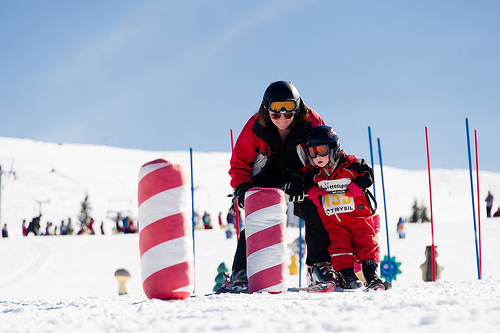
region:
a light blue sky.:
[21, 0, 162, 95]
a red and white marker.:
[133, 157, 196, 302]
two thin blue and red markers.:
[462, 114, 489, 282]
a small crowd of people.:
[0, 207, 113, 242]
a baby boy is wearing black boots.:
[332, 255, 387, 295]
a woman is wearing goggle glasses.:
[266, 105, 299, 121]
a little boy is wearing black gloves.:
[281, 172, 311, 204]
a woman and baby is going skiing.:
[131, 74, 416, 326]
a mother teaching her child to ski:
[227, 74, 397, 296]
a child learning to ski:
[293, 123, 393, 298]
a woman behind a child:
[219, 83, 392, 299]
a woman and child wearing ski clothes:
[225, 75, 397, 297]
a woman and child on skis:
[212, 75, 392, 308]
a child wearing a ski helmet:
[301, 120, 341, 170]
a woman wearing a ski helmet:
[255, 73, 307, 129]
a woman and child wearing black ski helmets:
[253, 79, 338, 170]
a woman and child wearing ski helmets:
[258, 75, 339, 175]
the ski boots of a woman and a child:
[303, 258, 390, 297]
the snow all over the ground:
[0, 138, 497, 332]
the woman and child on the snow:
[213, 79, 378, 287]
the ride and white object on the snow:
[243, 184, 286, 295]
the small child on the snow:
[288, 125, 385, 290]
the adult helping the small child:
[219, 80, 325, 290]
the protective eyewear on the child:
[305, 143, 330, 158]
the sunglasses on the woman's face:
[266, 110, 293, 119]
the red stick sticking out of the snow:
[423, 124, 435, 282]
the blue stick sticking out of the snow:
[463, 117, 481, 279]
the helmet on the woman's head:
[263, 80, 298, 102]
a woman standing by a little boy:
[223, 75, 413, 297]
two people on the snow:
[218, 85, 400, 300]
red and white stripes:
[133, 160, 195, 310]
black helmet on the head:
[300, 125, 340, 168]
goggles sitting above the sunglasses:
[258, 97, 299, 125]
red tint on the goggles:
[306, 143, 330, 159]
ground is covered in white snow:
[1, 136, 488, 331]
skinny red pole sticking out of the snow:
[418, 126, 441, 283]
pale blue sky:
[1, 2, 499, 175]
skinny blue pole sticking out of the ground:
[376, 134, 398, 289]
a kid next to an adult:
[220, 71, 397, 304]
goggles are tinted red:
[300, 140, 330, 160]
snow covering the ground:
[2, 136, 498, 331]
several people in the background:
[2, 206, 231, 238]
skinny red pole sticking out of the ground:
[421, 124, 446, 280]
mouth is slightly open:
[314, 156, 328, 168]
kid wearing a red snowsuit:
[288, 129, 400, 296]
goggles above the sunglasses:
[261, 96, 302, 125]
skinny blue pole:
[375, 135, 407, 286]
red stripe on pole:
[138, 163, 181, 203]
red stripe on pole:
[140, 213, 189, 259]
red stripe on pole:
[145, 265, 190, 295]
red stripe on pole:
[246, 188, 282, 218]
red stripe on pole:
[244, 223, 283, 256]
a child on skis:
[288, 126, 388, 296]